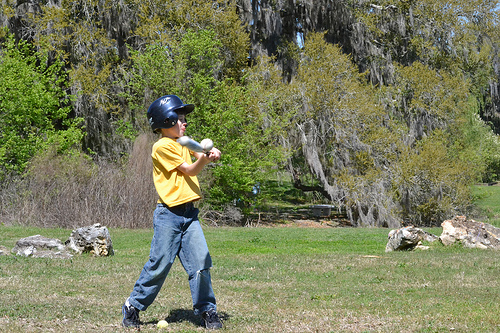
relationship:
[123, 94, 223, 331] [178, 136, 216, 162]
boy holding bat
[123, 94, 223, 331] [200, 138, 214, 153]
boy hitting ball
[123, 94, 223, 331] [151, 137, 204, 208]
boy wearing shirt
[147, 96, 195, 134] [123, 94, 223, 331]
helmet on boy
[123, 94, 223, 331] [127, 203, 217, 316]
boy wearing jeans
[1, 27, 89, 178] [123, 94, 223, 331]
tree behind boy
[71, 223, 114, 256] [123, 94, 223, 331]
rock behind boy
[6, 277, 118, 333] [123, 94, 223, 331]
grass behind boy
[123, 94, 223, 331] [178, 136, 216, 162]
boy swinging bat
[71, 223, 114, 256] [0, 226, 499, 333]
rock on ground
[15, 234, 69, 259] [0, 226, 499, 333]
rock on ground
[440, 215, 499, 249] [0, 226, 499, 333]
rock on ground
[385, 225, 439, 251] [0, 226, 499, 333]
rock on ground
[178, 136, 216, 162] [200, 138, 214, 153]
bat hitting ball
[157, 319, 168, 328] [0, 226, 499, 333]
ball on ground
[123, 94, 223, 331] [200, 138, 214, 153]
boy playing ball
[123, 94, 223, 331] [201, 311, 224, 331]
boy wearing shoe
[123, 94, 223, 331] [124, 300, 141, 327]
boy wearing shoe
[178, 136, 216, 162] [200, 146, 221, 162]
bat in hands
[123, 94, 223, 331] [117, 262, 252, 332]
boy on grass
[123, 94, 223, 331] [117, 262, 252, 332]
boy in grass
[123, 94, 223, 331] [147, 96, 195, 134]
boy wearing helmet